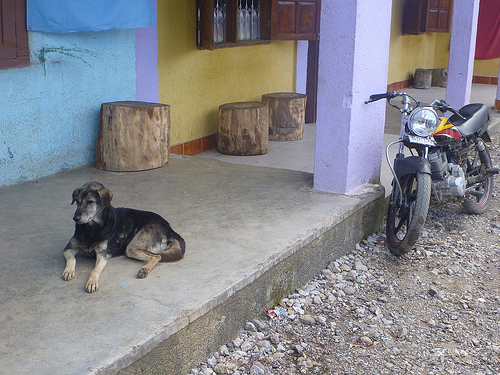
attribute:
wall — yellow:
[207, 60, 268, 76]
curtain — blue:
[22, 2, 159, 35]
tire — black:
[446, 143, 495, 214]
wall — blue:
[1, 38, 129, 181]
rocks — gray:
[305, 283, 357, 308]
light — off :
[406, 104, 443, 140]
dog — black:
[43, 176, 177, 271]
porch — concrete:
[2, 152, 384, 373]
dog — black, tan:
[20, 188, 225, 302]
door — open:
[297, 8, 312, 127]